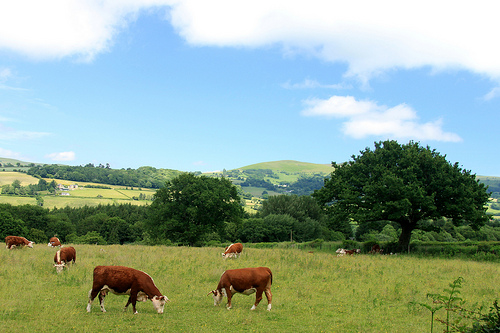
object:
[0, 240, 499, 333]
grass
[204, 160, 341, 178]
hill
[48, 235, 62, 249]
cow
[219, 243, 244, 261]
cows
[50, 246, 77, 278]
cows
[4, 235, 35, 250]
brown cow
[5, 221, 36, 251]
cow grazing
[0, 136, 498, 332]
in field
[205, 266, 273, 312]
cow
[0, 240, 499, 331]
field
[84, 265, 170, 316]
cow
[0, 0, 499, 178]
sky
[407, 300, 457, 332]
weeds/field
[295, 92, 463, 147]
clouds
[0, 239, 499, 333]
ground